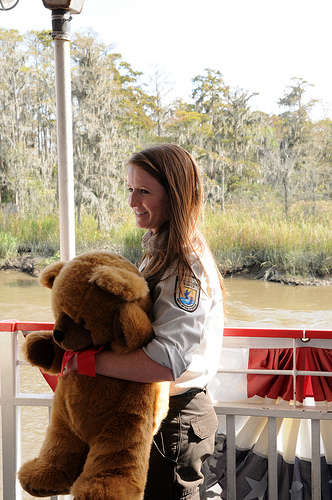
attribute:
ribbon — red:
[58, 347, 102, 374]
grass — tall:
[198, 193, 329, 281]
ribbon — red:
[46, 342, 119, 384]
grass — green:
[282, 234, 294, 268]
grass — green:
[237, 230, 241, 257]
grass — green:
[250, 231, 259, 252]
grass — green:
[268, 234, 276, 268]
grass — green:
[304, 230, 309, 266]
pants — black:
[145, 383, 224, 499]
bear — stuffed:
[21, 240, 157, 498]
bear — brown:
[32, 244, 175, 471]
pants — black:
[156, 407, 210, 494]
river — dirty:
[237, 267, 301, 320]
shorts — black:
[147, 388, 218, 497]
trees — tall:
[78, 29, 182, 140]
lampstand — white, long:
[55, 38, 80, 260]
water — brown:
[0, 282, 331, 467]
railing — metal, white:
[0, 320, 331, 498]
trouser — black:
[126, 377, 227, 496]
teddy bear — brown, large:
[16, 249, 171, 498]